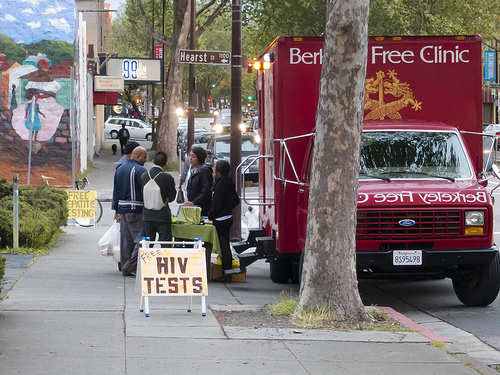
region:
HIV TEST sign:
[99, 216, 239, 318]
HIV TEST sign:
[126, 226, 207, 294]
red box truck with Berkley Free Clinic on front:
[252, 31, 497, 285]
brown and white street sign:
[171, 43, 265, 84]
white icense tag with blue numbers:
[388, 240, 445, 270]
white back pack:
[138, 163, 172, 220]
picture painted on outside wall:
[1, 3, 84, 205]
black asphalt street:
[450, 303, 493, 335]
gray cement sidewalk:
[19, 276, 155, 372]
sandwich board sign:
[130, 228, 235, 343]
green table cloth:
[168, 192, 233, 270]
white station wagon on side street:
[104, 111, 190, 162]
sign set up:
[134, 247, 209, 298]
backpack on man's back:
[138, 171, 167, 213]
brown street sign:
[176, 46, 234, 66]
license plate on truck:
[392, 246, 424, 266]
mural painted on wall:
[0, 1, 75, 184]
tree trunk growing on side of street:
[299, 5, 377, 327]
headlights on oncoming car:
[209, 119, 252, 136]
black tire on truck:
[448, 242, 499, 315]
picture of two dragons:
[353, 62, 424, 125]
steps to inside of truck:
[219, 222, 280, 286]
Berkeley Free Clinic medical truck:
[250, 35, 498, 307]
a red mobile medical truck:
[254, 34, 499, 311]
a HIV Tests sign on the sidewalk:
[137, 235, 209, 318]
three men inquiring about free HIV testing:
[110, 140, 177, 279]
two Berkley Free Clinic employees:
[177, 146, 240, 284]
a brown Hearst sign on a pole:
[177, 48, 232, 67]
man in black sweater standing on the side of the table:
[137, 151, 174, 237]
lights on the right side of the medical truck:
[245, 50, 272, 67]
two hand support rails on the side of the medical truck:
[235, 151, 270, 202]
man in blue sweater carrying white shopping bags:
[96, 145, 146, 276]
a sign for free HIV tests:
[124, 236, 229, 313]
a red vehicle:
[276, 0, 491, 293]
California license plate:
[368, 241, 458, 276]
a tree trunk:
[299, 3, 377, 322]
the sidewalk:
[43, 241, 110, 373]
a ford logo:
[387, 214, 449, 231]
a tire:
[446, 238, 496, 342]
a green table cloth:
[173, 215, 228, 267]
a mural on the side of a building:
[6, 21, 79, 196]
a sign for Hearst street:
[158, 35, 246, 74]